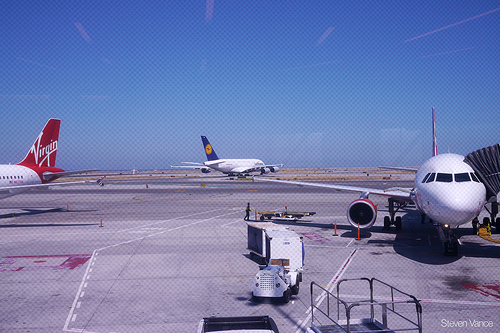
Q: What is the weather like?
A: It is clear.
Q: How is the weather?
A: It is clear.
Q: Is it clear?
A: Yes, it is clear.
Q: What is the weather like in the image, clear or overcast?
A: It is clear.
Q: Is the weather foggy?
A: No, it is clear.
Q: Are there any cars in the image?
A: No, there are no cars.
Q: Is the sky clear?
A: Yes, the sky is clear.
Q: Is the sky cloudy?
A: No, the sky is clear.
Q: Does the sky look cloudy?
A: No, the sky is clear.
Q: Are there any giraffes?
A: No, there are no giraffes.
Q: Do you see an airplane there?
A: Yes, there is an airplane.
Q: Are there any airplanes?
A: Yes, there is an airplane.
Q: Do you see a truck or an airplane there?
A: Yes, there is an airplane.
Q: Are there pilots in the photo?
A: No, there are no pilots.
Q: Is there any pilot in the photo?
A: No, there are no pilots.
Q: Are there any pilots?
A: No, there are no pilots.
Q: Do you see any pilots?
A: No, there are no pilots.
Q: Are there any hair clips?
A: No, there are no hair clips.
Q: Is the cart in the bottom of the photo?
A: Yes, the cart is in the bottom of the image.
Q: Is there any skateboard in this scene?
A: No, there are no skateboards.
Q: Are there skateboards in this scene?
A: No, there are no skateboards.